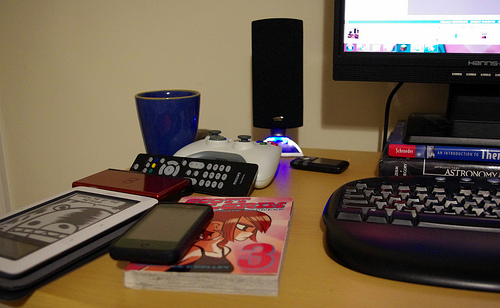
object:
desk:
[0, 128, 498, 308]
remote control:
[128, 150, 264, 199]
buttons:
[214, 181, 226, 190]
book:
[370, 153, 496, 178]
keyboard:
[317, 175, 499, 295]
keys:
[386, 212, 421, 227]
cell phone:
[105, 193, 215, 267]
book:
[116, 188, 298, 298]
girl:
[132, 205, 278, 276]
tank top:
[159, 240, 239, 276]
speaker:
[244, 13, 303, 163]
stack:
[378, 126, 498, 179]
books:
[379, 139, 498, 167]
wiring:
[376, 82, 404, 156]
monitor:
[331, 0, 499, 89]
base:
[253, 133, 307, 162]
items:
[2, 0, 499, 307]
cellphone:
[288, 152, 358, 177]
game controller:
[173, 123, 282, 191]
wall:
[0, 0, 448, 221]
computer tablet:
[0, 184, 159, 277]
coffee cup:
[129, 88, 204, 158]